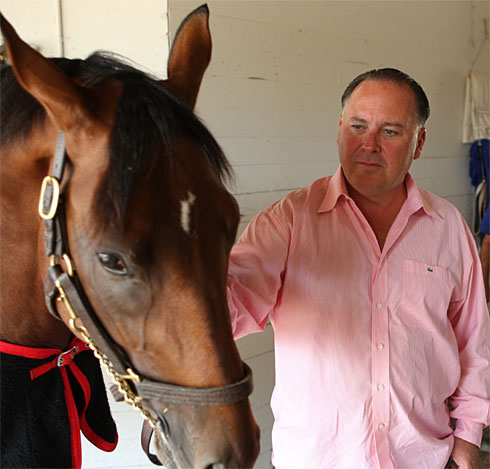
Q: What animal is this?
A: Horse.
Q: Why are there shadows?
A: Light.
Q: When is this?
A: Daytime.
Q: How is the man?
A: Motionless.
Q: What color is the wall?
A: White.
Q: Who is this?
A: Man.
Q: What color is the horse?
A: Brown.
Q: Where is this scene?
A: At a ranch.